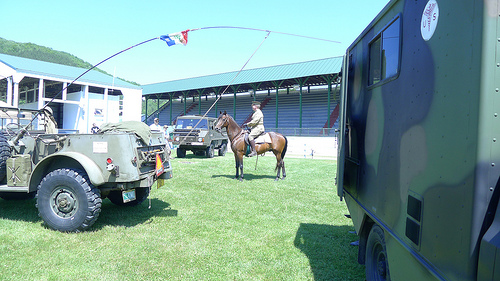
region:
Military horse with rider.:
[208, 93, 307, 187]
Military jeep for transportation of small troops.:
[0, 88, 174, 231]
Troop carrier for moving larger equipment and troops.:
[173, 111, 235, 166]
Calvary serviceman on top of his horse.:
[242, 95, 270, 166]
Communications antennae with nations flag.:
[14, 17, 343, 152]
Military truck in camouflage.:
[310, 0, 496, 279]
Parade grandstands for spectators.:
[146, 57, 348, 147]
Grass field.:
[171, 173, 337, 276]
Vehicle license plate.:
[121, 186, 145, 206]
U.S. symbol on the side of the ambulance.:
[410, 0, 452, 49]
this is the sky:
[59, 2, 131, 37]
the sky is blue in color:
[271, 3, 296, 21]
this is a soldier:
[246, 100, 261, 135]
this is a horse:
[221, 114, 241, 136]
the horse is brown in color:
[276, 137, 283, 147]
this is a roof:
[258, 65, 311, 75]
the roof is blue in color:
[273, 66, 319, 80]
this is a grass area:
[194, 195, 283, 257]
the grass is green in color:
[204, 208, 224, 237]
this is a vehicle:
[23, 120, 147, 207]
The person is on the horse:
[230, 69, 300, 199]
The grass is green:
[220, 169, 292, 279]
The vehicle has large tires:
[16, 135, 142, 268]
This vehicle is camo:
[288, 52, 498, 227]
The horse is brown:
[209, 102, 292, 160]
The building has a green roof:
[2, 42, 138, 103]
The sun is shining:
[184, 187, 331, 263]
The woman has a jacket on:
[242, 104, 264, 154]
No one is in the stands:
[164, 41, 429, 244]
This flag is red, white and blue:
[143, 18, 211, 64]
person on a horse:
[207, 100, 297, 182]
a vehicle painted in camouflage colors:
[330, 15, 496, 268]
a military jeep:
[13, 95, 181, 224]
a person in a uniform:
[240, 95, 266, 166]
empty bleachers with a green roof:
[140, 60, 342, 134]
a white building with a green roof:
[4, 50, 153, 142]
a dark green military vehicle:
[167, 110, 235, 157]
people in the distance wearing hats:
[146, 112, 171, 144]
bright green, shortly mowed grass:
[174, 179, 337, 272]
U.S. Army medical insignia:
[419, 5, 445, 45]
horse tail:
[276, 132, 293, 162]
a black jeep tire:
[37, 161, 99, 233]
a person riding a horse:
[236, 96, 267, 156]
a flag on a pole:
[160, 22, 202, 50]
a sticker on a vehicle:
[410, 8, 455, 38]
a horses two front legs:
[228, 155, 249, 180]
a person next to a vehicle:
[149, 112, 168, 134]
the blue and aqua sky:
[43, 17, 113, 45]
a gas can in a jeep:
[0, 147, 30, 189]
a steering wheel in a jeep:
[7, 122, 39, 145]